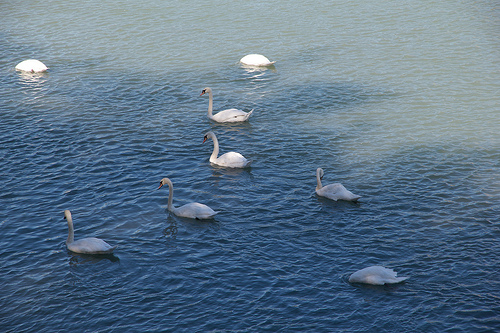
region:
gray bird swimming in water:
[48, 208, 112, 256]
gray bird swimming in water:
[20, 44, 43, 94]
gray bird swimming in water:
[145, 176, 234, 242]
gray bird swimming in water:
[350, 249, 419, 295]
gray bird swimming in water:
[304, 160, 357, 206]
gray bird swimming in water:
[195, 133, 268, 193]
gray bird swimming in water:
[198, 74, 262, 122]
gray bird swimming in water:
[220, 46, 286, 76]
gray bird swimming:
[54, 205, 111, 251]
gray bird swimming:
[143, 173, 216, 239]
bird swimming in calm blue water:
[196, 86, 253, 122]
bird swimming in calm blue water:
[310, 165, 360, 200]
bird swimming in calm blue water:
[342, 260, 404, 285]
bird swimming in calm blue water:
[57, 207, 112, 253]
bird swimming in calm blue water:
[152, 175, 217, 220]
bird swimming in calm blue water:
[12, 55, 44, 75]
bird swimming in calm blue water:
[237, 50, 272, 65]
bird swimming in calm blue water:
[202, 131, 252, 169]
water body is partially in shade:
[5, 4, 475, 321]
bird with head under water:
[347, 256, 410, 292]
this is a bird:
[322, 238, 421, 320]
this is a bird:
[302, 156, 357, 227]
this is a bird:
[50, 187, 129, 278]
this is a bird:
[148, 165, 219, 237]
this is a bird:
[191, 118, 255, 181]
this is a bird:
[179, 72, 265, 146]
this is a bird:
[216, 43, 296, 91]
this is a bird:
[3, 45, 65, 95]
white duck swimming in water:
[12, 52, 58, 77]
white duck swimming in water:
[242, 47, 274, 74]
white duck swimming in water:
[199, 83, 258, 128]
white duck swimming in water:
[204, 132, 246, 174]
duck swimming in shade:
[52, 206, 117, 262]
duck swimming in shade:
[157, 174, 222, 229]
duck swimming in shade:
[313, 159, 365, 209]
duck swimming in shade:
[352, 259, 413, 286]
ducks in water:
[13, 39, 411, 294]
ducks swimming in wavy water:
[17, 44, 412, 300]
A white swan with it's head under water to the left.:
[15, 57, 47, 72]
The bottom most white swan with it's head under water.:
[347, 265, 407, 286]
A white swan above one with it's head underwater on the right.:
[315, 165, 362, 202]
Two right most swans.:
[311, 166, 406, 286]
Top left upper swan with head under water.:
[11, 59, 48, 74]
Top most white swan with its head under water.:
[238, 51, 276, 68]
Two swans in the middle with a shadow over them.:
[196, 84, 254, 169]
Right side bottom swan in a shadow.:
[62, 208, 117, 255]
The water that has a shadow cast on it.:
[3, 46, 492, 331]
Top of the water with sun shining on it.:
[2, 2, 499, 75]